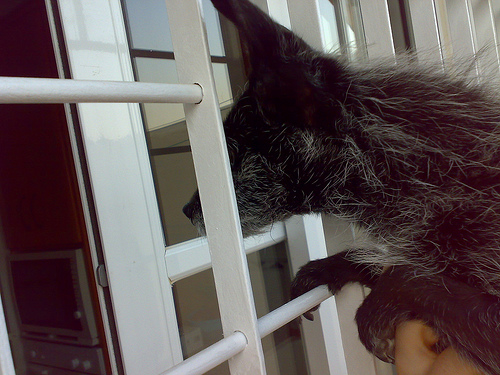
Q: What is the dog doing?
A: Looking in a window.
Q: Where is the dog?
A: Outside of the window.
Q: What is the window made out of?
A: Glass.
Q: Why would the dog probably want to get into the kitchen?
A: To eat.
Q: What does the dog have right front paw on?
A: White bar.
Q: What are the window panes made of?
A: Glass.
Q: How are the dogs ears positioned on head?
A: Straight up.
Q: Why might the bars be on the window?
A: To prevent burglaries.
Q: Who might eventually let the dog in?
A: Owner.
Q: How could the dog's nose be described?
A: Pointed.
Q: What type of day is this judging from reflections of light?
A: Sunny.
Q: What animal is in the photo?
A: A dog.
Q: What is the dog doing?
A: Looking through a window.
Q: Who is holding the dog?
A: A person.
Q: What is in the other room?
A: A television.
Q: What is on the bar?
A: The paw.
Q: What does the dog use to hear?
A: The ear.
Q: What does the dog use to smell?
A: The nose.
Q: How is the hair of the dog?
A: Rakish.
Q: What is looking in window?
A: Dog.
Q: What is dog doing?
A: Looking in window.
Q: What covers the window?
A: Bars.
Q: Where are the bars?
A: Over window.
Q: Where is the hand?
A: Under dog.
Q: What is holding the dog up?
A: Hand.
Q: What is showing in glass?
A: Reflection.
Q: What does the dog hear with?
A: Ears.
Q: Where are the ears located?
A: On dogs head.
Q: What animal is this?
A: A dog.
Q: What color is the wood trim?
A: White.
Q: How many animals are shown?
A: 1.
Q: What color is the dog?
A: Black and white.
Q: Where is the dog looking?
A: Into the room.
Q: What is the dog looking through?
A: A window.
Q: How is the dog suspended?
A: Someone is holding the dog up.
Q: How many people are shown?
A: 0.